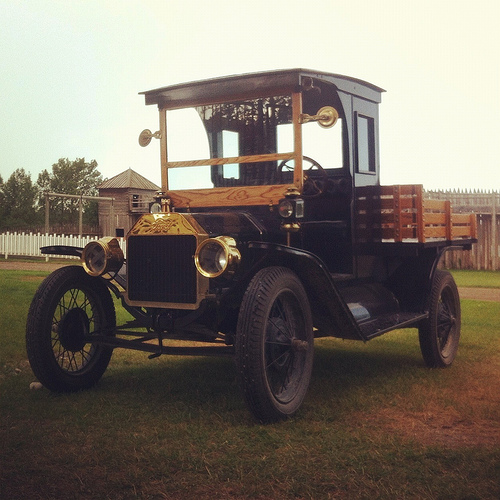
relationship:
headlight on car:
[79, 235, 123, 279] [24, 60, 475, 422]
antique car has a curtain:
[23, 66, 480, 421] [233, 120, 280, 177]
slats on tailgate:
[422, 212, 476, 227] [377, 181, 482, 244]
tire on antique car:
[423, 261, 465, 365] [23, 66, 480, 416]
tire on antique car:
[236, 261, 319, 422] [23, 66, 480, 416]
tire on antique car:
[26, 265, 118, 387] [23, 66, 480, 416]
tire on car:
[26, 265, 118, 387] [24, 60, 475, 422]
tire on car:
[236, 261, 319, 422] [24, 60, 475, 422]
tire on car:
[25, 265, 116, 394] [26, 70, 468, 391]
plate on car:
[56, 304, 92, 354] [24, 60, 475, 422]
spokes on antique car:
[50, 290, 108, 371] [23, 66, 480, 421]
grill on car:
[116, 232, 203, 303] [42, 54, 497, 383]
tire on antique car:
[419, 270, 462, 367] [23, 66, 480, 421]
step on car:
[338, 269, 419, 344] [36, 32, 474, 414]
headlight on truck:
[194, 234, 241, 279] [25, 68, 483, 421]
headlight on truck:
[80, 236, 123, 277] [25, 68, 483, 421]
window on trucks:
[165, 93, 297, 185] [20, 57, 482, 425]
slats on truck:
[422, 212, 470, 224] [25, 68, 483, 421]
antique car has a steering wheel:
[23, 66, 480, 421] [269, 135, 351, 210]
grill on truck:
[125, 233, 197, 306] [24, 43, 471, 428]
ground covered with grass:
[1, 255, 499, 495] [3, 257, 498, 499]